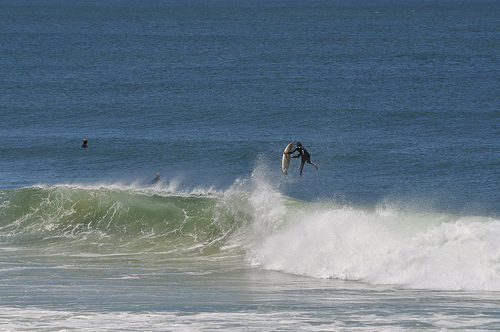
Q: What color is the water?
A: Blue.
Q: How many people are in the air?
A: One.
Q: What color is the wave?
A: White.